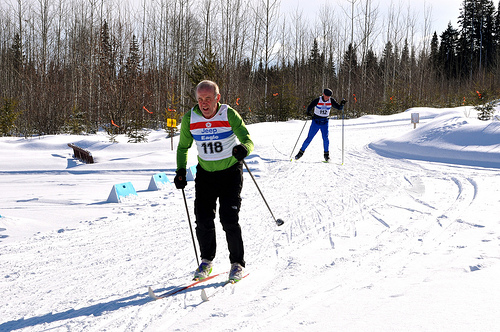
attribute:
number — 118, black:
[200, 142, 224, 153]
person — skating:
[178, 81, 256, 287]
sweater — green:
[175, 109, 253, 169]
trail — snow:
[0, 108, 488, 332]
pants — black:
[194, 168, 246, 267]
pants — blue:
[298, 119, 332, 154]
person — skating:
[295, 86, 345, 160]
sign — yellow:
[167, 118, 175, 128]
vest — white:
[189, 103, 240, 162]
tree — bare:
[311, 39, 321, 117]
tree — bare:
[337, 44, 364, 120]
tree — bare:
[356, 53, 386, 118]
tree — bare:
[380, 44, 400, 114]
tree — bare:
[400, 44, 410, 105]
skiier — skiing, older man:
[295, 86, 345, 160]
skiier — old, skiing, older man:
[178, 81, 256, 287]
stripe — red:
[188, 120, 232, 130]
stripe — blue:
[190, 130, 234, 141]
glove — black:
[231, 144, 247, 162]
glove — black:
[174, 168, 188, 189]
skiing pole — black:
[241, 158, 284, 226]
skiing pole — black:
[181, 187, 200, 267]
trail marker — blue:
[106, 182, 139, 204]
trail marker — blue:
[147, 172, 171, 192]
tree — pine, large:
[438, 20, 461, 78]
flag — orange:
[110, 120, 121, 128]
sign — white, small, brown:
[410, 113, 421, 125]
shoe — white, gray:
[227, 262, 245, 283]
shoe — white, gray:
[193, 261, 212, 281]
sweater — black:
[306, 97, 343, 122]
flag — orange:
[353, 94, 359, 104]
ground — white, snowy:
[0, 107, 500, 329]